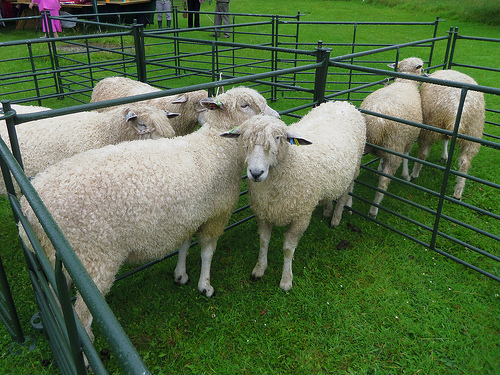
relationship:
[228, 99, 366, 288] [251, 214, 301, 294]
sheep has front legs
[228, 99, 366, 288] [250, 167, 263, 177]
sheep has nose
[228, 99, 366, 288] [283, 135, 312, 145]
sheep has ear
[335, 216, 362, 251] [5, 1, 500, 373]
manure on grass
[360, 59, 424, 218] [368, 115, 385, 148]
sheep has tail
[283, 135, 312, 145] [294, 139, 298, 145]
ear has tag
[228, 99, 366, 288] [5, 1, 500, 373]
sheep on grass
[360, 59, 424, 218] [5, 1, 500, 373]
sheep standing on grass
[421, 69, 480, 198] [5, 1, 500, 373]
sheep standing on grass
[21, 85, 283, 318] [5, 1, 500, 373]
sheep standing on grass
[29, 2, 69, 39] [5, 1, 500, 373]
person standing on grass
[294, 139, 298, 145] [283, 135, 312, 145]
tag on ear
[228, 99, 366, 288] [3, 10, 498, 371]
sheep standing inside cage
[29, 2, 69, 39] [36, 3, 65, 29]
person wearing dress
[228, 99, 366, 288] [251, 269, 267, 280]
sheep has hooves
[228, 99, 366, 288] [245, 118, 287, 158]
sheep have hair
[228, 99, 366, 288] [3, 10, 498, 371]
sheep in cage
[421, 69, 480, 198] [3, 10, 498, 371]
sheep in cage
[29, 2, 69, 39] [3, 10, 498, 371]
person behind cage